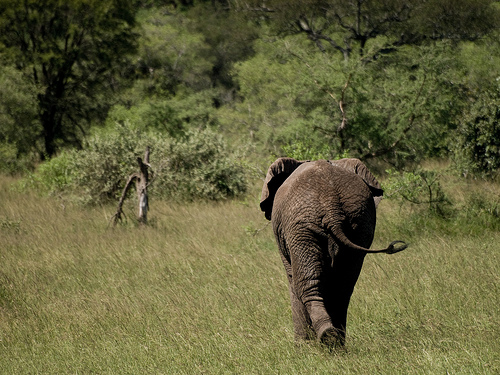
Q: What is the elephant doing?
A: Walking.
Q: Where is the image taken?
A: In forest.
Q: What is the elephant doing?
A: Walking.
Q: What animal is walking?
A: An elephant.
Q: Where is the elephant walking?
A: In a field.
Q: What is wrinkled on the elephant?
A: Its skin.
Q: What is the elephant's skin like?
A: Wrinkled.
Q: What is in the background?
A: Trees.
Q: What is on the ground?
A: A fallen tree.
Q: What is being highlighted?
A: An elephant butt.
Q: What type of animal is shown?
A: Elephant.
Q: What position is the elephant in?
A: Standing.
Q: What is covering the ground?
A: Grass.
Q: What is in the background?
A: Trees.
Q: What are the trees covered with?
A: Leaves.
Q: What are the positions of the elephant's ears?
A: Out.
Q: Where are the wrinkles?
A: Covering the elephant.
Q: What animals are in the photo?
A: Elephants.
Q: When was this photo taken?
A: Daytime.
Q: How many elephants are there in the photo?
A: One.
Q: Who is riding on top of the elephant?
A: No one.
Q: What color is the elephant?
A: Grey.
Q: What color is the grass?
A: Green.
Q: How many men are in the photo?
A: Zero.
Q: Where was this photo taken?
A: Near elephant.